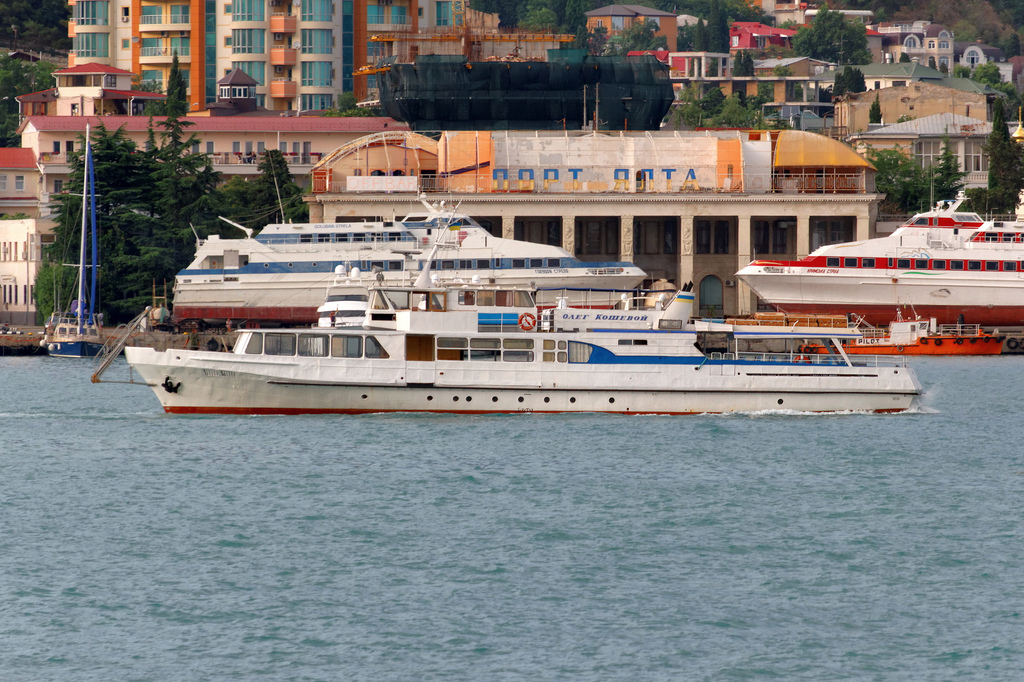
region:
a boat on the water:
[107, 256, 933, 428]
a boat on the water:
[142, 217, 621, 315]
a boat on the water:
[744, 211, 1020, 304]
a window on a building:
[312, 64, 339, 83]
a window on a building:
[312, 76, 331, 106]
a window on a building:
[77, 69, 94, 83]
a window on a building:
[106, 76, 125, 89]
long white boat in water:
[98, 265, 934, 474]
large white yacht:
[215, 193, 648, 298]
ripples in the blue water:
[51, 467, 127, 528]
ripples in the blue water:
[791, 509, 864, 566]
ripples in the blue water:
[358, 563, 410, 606]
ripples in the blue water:
[543, 521, 602, 566]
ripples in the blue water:
[256, 446, 333, 510]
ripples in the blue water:
[224, 601, 311, 650]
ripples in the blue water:
[107, 427, 169, 481]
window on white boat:
[264, 329, 298, 356]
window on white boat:
[296, 331, 330, 358]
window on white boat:
[328, 333, 368, 358]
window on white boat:
[362, 329, 394, 360]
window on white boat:
[406, 331, 435, 362]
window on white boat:
[434, 335, 470, 360]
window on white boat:
[468, 333, 504, 358]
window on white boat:
[503, 339, 537, 364]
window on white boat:
[540, 337, 572, 364]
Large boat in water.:
[116, 316, 932, 430]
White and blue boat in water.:
[53, 126, 110, 367]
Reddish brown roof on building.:
[46, 101, 411, 136]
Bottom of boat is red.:
[177, 405, 684, 425]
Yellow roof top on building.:
[757, 119, 878, 168]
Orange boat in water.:
[812, 315, 1015, 360]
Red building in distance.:
[730, 12, 806, 50]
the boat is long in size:
[115, 278, 945, 447]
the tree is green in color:
[104, 135, 194, 238]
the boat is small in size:
[856, 315, 1009, 360]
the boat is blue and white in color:
[50, 120, 118, 365]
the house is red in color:
[730, 13, 795, 53]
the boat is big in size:
[747, 205, 1023, 313]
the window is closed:
[297, 28, 342, 57]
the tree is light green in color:
[874, 155, 923, 204]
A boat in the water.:
[137, 298, 931, 441]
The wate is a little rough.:
[86, 446, 984, 665]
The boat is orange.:
[808, 307, 1017, 362]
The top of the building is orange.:
[367, 124, 871, 178]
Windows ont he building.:
[235, 127, 318, 157]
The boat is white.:
[122, 302, 913, 446]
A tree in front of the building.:
[91, 107, 260, 330]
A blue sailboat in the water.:
[37, 149, 107, 375]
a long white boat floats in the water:
[122, 304, 928, 419]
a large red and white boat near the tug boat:
[738, 202, 1020, 323]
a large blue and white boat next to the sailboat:
[150, 213, 638, 316]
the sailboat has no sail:
[34, 120, 107, 361]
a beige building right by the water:
[299, 126, 889, 320]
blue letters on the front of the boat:
[561, 310, 654, 327]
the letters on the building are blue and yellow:
[486, 164, 703, 200]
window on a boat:
[429, 325, 480, 360]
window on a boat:
[438, 338, 484, 365]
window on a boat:
[470, 329, 502, 368]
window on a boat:
[502, 332, 542, 353]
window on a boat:
[499, 344, 534, 363]